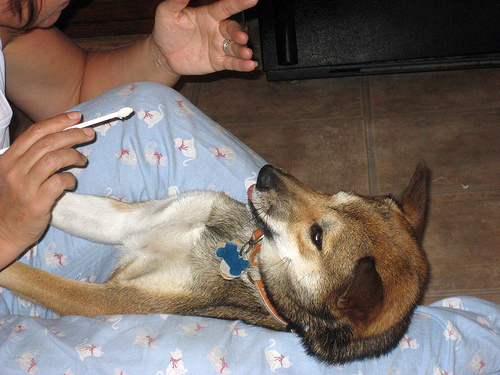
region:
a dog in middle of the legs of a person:
[9, 157, 466, 353]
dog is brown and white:
[27, 148, 449, 357]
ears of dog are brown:
[330, 162, 445, 320]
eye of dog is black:
[299, 210, 342, 253]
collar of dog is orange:
[243, 227, 285, 332]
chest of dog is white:
[102, 186, 227, 303]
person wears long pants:
[6, 3, 491, 370]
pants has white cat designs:
[27, 319, 287, 373]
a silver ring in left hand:
[145, 0, 255, 75]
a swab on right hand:
[3, 85, 133, 251]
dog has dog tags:
[219, 222, 256, 283]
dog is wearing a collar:
[250, 293, 290, 320]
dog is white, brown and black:
[167, 268, 261, 327]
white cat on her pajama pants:
[138, 100, 170, 137]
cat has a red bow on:
[170, 137, 201, 164]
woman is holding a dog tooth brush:
[20, 97, 147, 137]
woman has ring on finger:
[218, 28, 250, 50]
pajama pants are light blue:
[166, 107, 231, 182]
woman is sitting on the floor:
[11, 291, 498, 374]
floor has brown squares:
[268, 60, 496, 157]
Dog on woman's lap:
[28, 167, 432, 357]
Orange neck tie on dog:
[243, 225, 285, 325]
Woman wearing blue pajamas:
[3, 88, 490, 374]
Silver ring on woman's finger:
[224, 40, 229, 55]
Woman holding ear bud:
[65, 108, 135, 130]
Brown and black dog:
[194, 163, 441, 360]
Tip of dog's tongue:
[244, 184, 255, 196]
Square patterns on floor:
[261, 67, 498, 285]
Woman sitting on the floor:
[0, 0, 498, 372]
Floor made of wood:
[218, 80, 498, 270]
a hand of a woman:
[150, 2, 267, 79]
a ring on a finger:
[220, 36, 230, 60]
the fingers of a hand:
[6, 105, 95, 214]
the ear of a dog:
[332, 254, 389, 321]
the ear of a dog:
[395, 158, 437, 230]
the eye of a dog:
[303, 216, 328, 256]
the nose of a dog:
[254, 159, 276, 194]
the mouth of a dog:
[247, 182, 278, 240]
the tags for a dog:
[217, 237, 253, 288]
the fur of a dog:
[163, 199, 238, 239]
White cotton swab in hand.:
[75, 100, 148, 140]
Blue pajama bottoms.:
[7, 80, 498, 373]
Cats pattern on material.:
[141, 108, 206, 174]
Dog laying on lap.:
[50, 158, 430, 358]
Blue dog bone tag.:
[215, 236, 247, 280]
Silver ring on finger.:
[209, 20, 254, 76]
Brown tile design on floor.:
[278, 78, 498, 196]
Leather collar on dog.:
[245, 227, 287, 332]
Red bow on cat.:
[137, 103, 167, 128]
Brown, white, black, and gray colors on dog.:
[3, 161, 435, 361]